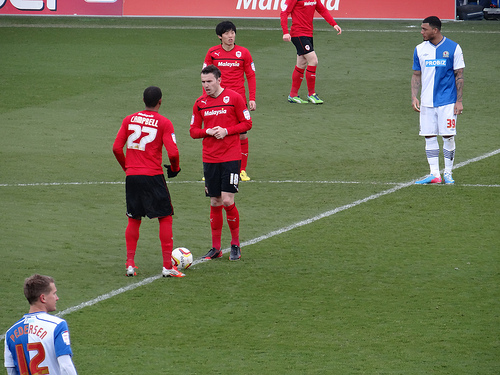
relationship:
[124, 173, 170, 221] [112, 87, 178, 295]
black on player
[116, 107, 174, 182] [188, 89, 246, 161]
red soccer jersey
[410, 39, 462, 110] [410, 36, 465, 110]
blue soccer blue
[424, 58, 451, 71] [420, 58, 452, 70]
logo name writing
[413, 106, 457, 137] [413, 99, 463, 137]
white soccer white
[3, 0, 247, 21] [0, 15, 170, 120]
wall behind field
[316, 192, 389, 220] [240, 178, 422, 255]
white chalk white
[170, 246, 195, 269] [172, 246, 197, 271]
ball red ball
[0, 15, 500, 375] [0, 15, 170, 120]
field grass field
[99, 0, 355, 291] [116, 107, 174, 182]
soccer players red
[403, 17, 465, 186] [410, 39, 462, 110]
players wearing blue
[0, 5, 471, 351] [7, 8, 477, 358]
professional soccer players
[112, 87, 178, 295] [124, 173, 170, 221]
player wearing black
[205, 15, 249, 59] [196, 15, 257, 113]
asian soccer asian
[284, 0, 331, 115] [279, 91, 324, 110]
player wearing yellow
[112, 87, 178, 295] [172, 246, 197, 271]
player kick ball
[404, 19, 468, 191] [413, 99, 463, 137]
player wearing white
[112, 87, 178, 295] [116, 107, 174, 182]
player in red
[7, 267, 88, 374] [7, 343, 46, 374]
player number 12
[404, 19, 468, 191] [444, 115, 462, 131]
player number number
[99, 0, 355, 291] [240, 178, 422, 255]
soccer ball white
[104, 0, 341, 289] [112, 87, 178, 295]
soccer red player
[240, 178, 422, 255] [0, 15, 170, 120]
white down field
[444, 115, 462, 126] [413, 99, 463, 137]
number on white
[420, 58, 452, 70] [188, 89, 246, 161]
writing on jersey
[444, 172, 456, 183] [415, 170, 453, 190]
blue red cleats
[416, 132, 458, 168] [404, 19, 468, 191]
leg of player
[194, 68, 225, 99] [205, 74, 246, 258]
head of player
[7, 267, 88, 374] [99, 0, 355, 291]
player playing soccer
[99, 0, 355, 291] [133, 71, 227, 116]
soccer players talking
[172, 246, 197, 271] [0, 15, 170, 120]
ball on field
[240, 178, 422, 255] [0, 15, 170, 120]
white on field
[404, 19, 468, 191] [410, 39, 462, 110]
player in blue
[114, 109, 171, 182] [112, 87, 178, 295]
back of player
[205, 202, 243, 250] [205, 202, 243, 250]
red soccer red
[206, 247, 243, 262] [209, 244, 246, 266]
black soccer cleats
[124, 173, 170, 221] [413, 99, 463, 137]
black soccer white